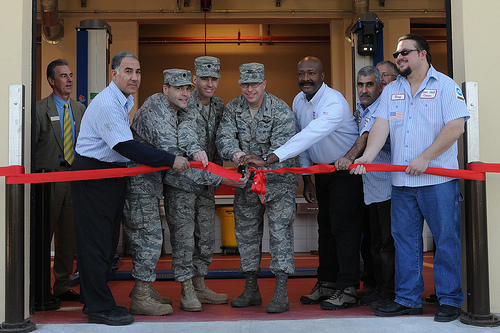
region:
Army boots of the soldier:
[127, 274, 173, 319]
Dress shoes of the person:
[81, 300, 141, 325]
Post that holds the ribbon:
[3, 160, 41, 327]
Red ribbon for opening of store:
[1, 160, 498, 191]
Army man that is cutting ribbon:
[218, 51, 302, 327]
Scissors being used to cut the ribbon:
[233, 152, 265, 192]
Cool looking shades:
[391, 45, 421, 65]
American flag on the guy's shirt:
[388, 108, 402, 119]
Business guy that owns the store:
[38, 53, 88, 246]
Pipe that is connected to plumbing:
[152, 24, 314, 49]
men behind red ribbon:
[26, 31, 496, 323]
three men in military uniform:
[129, 54, 299, 318]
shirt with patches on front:
[370, 70, 465, 186]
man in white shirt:
[282, 58, 352, 173]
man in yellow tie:
[39, 59, 90, 165]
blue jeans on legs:
[394, 181, 467, 306]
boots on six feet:
[130, 268, 290, 318]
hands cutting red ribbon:
[223, 156, 272, 194]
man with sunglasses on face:
[392, 35, 429, 80]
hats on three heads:
[164, 55, 265, 110]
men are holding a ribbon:
[0, 25, 479, 298]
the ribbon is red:
[22, 133, 490, 225]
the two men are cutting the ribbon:
[208, 43, 346, 213]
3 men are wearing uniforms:
[140, 31, 313, 329]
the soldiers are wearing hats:
[145, 43, 287, 101]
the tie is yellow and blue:
[49, 99, 86, 166]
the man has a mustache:
[288, 74, 327, 98]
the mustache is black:
[294, 75, 319, 94]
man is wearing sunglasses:
[380, 25, 427, 71]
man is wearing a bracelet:
[253, 141, 281, 176]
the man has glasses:
[380, 39, 462, 319]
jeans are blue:
[391, 191, 456, 296]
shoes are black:
[380, 294, 460, 329]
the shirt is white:
[291, 94, 356, 166]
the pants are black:
[317, 186, 363, 283]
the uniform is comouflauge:
[229, 99, 294, 269]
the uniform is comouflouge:
[179, 109, 218, 286]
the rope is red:
[51, 146, 497, 211]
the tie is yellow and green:
[57, 106, 76, 162]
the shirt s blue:
[55, 96, 79, 141]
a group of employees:
[33, 19, 457, 273]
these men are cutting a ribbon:
[67, 53, 432, 243]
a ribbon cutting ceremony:
[38, 8, 452, 198]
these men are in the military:
[134, 46, 308, 328]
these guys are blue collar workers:
[343, 36, 470, 297]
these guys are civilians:
[42, 54, 139, 316]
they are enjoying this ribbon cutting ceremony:
[53, 41, 440, 260]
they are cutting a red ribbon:
[5, 132, 490, 200]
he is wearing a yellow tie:
[43, 56, 88, 169]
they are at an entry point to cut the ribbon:
[53, 18, 415, 305]